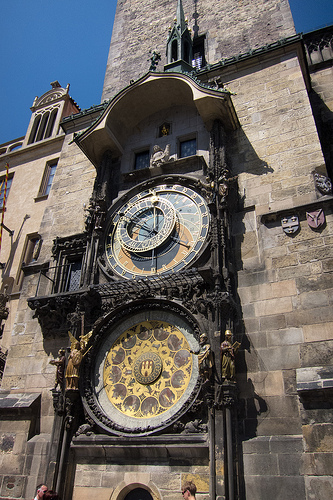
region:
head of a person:
[176, 477, 203, 498]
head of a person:
[34, 482, 51, 499]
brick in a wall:
[234, 450, 282, 478]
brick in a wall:
[266, 432, 307, 453]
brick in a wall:
[241, 436, 271, 455]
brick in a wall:
[277, 449, 323, 478]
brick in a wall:
[262, 326, 307, 349]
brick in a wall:
[248, 293, 293, 320]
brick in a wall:
[271, 261, 312, 283]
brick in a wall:
[236, 266, 272, 289]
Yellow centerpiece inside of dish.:
[134, 353, 161, 384]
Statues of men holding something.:
[193, 334, 239, 387]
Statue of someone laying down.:
[175, 418, 222, 442]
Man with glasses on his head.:
[179, 483, 191, 490]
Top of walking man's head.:
[29, 481, 48, 495]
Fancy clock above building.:
[108, 184, 184, 265]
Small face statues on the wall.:
[269, 202, 323, 234]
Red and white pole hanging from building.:
[0, 156, 21, 281]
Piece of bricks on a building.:
[277, 423, 314, 463]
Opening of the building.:
[103, 470, 160, 494]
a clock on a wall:
[96, 180, 211, 279]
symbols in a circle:
[93, 321, 198, 420]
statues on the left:
[190, 326, 241, 387]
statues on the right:
[47, 330, 88, 403]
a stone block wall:
[243, 271, 332, 353]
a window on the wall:
[52, 242, 90, 297]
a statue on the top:
[147, 142, 171, 167]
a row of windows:
[25, 105, 58, 145]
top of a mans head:
[171, 482, 201, 498]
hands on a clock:
[119, 200, 191, 248]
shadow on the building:
[249, 132, 277, 164]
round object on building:
[123, 347, 165, 394]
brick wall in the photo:
[256, 424, 307, 483]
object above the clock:
[142, 131, 174, 173]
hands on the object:
[112, 189, 191, 259]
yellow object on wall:
[85, 315, 199, 428]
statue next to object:
[209, 326, 253, 380]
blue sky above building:
[11, 16, 68, 54]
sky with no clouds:
[33, 6, 86, 44]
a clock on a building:
[34, 91, 289, 340]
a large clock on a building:
[67, 174, 275, 376]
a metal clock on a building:
[62, 160, 272, 421]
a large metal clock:
[78, 143, 327, 375]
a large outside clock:
[55, 152, 275, 407]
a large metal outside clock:
[74, 157, 230, 384]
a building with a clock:
[57, 150, 287, 406]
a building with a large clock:
[83, 166, 255, 416]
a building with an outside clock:
[36, 158, 286, 359]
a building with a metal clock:
[67, 155, 269, 418]